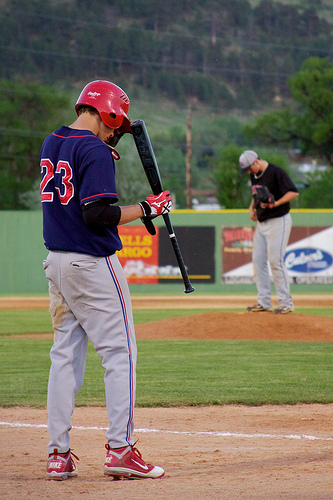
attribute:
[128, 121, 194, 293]
baseball bat — black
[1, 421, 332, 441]
line — white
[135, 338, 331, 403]
grass — patch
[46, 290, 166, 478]
legs — player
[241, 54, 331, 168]
tree — large and green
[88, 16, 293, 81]
power line — long, electrical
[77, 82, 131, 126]
helmet — red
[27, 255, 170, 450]
pants — gray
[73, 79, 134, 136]
helmet — red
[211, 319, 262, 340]
dirt — light, brown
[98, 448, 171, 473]
shoe — white, red, man's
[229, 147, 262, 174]
baseball cap — gray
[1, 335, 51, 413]
grass — patch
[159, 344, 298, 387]
grass — patch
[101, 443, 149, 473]
cleats — red, nike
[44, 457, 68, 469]
cleats — nike, red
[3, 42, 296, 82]
metal wire — silver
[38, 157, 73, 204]
number — red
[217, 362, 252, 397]
grass — patch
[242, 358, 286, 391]
patch — green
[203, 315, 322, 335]
mound — pitchers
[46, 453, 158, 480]
sneakers — red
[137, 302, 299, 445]
field — baseball